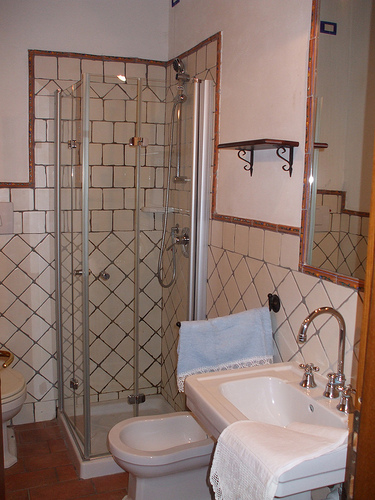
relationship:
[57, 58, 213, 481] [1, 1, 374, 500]
shower in bathroom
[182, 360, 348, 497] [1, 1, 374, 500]
sink in a bathroom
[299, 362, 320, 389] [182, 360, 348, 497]
handle on sink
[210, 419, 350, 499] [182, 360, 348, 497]
towel on side of sink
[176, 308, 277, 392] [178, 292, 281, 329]
towel on rack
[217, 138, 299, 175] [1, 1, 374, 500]
shelf in bathroom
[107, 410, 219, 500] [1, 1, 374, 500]
bidet in bathroom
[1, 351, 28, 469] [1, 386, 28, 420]
toilet has bowl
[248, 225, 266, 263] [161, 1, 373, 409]
tile on wall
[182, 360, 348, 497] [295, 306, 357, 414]
sink has fixtures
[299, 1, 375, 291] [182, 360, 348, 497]
mirror above sink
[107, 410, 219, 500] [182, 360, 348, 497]
bidet beside sink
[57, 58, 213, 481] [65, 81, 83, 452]
shower has doors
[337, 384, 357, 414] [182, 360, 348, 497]
handle on sink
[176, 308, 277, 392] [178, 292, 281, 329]
towel hanging on rack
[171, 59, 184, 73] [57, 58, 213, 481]
showerhead in shower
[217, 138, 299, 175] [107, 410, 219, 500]
shelf above bidet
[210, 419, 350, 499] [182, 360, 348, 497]
towel on sink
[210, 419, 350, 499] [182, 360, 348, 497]
towel on a sink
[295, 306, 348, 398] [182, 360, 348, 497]
faucet on sink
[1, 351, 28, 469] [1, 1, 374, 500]
toilet in a bathroom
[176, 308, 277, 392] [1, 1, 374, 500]
towel in bathroom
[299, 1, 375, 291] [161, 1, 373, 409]
mirror on wall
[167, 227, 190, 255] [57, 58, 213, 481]
water control for shower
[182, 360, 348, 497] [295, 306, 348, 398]
sink has faucet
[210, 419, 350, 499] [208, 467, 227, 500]
towel has trim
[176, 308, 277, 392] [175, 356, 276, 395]
towel has trim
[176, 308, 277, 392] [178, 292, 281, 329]
towel hanging from rack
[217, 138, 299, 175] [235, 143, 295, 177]
shelf has supports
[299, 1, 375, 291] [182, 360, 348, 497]
mirror hanging over sink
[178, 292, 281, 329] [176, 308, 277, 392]
rack has towel